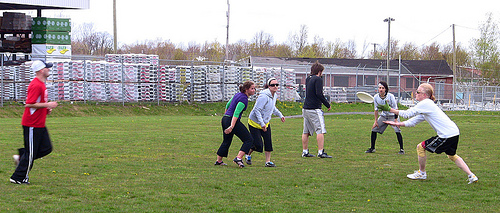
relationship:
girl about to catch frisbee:
[373, 79, 488, 188] [352, 89, 379, 107]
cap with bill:
[31, 59, 53, 74] [46, 62, 54, 66]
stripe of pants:
[26, 122, 36, 187] [10, 123, 53, 183]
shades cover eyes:
[265, 80, 281, 90] [258, 79, 297, 90]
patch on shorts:
[417, 138, 433, 158] [416, 136, 459, 153]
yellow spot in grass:
[367, 197, 374, 202] [0, 97, 499, 211]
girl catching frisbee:
[381, 82, 479, 185] [353, 89, 375, 104]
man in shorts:
[298, 64, 329, 159] [302, 108, 327, 136]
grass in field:
[204, 183, 303, 207] [3, 101, 490, 189]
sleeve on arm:
[231, 99, 245, 122] [221, 95, 249, 135]